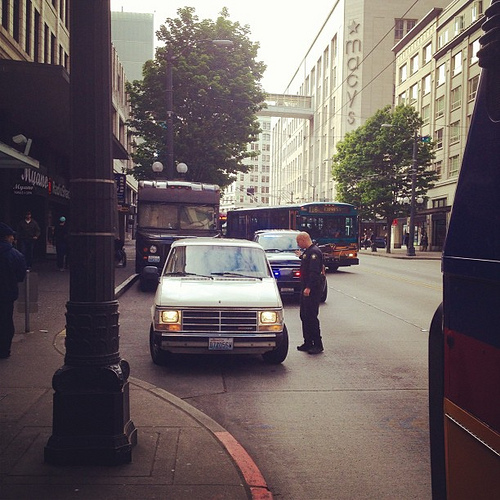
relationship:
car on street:
[148, 234, 293, 371] [97, 195, 448, 495]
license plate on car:
[206, 332, 238, 354] [148, 234, 293, 371]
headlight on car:
[153, 306, 182, 327] [148, 234, 293, 371]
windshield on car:
[160, 243, 274, 280] [148, 234, 293, 371]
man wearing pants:
[290, 228, 332, 357] [293, 288, 330, 356]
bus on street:
[223, 199, 362, 275] [97, 195, 448, 495]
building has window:
[386, 0, 498, 263] [398, 58, 410, 85]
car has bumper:
[148, 234, 293, 371] [148, 330, 287, 358]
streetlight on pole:
[149, 155, 165, 176] [163, 30, 238, 179]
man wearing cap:
[49, 210, 72, 275] [57, 214, 69, 226]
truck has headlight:
[130, 174, 230, 297] [144, 241, 164, 255]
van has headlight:
[130, 174, 230, 297] [144, 241, 164, 255]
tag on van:
[146, 253, 164, 266] [130, 174, 230, 297]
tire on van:
[135, 257, 154, 297] [130, 174, 230, 297]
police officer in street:
[290, 228, 332, 357] [97, 195, 448, 495]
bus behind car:
[223, 199, 362, 275] [247, 225, 332, 306]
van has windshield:
[130, 174, 230, 297] [133, 197, 223, 239]